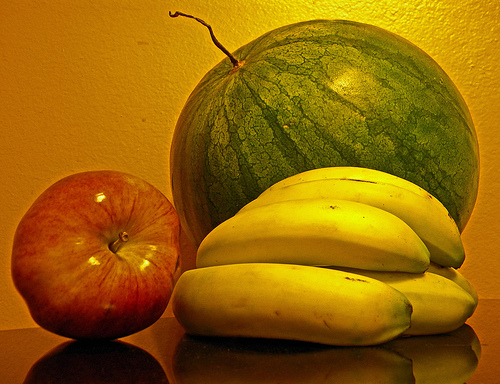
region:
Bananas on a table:
[170, 176, 485, 339]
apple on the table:
[12, 159, 184, 320]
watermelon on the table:
[158, 4, 488, 234]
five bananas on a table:
[173, 159, 497, 346]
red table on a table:
[13, 160, 203, 317]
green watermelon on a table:
[173, 15, 461, 207]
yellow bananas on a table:
[225, 186, 392, 289]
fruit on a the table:
[3, 0, 485, 324]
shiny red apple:
[16, 170, 176, 312]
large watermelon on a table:
[177, 65, 479, 216]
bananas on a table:
[177, 172, 480, 344]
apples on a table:
[12, 173, 178, 333]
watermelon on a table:
[151, 0, 486, 287]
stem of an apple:
[89, 216, 146, 258]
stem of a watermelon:
[166, 0, 246, 72]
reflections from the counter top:
[21, 340, 156, 382]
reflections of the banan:
[187, 335, 407, 380]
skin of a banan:
[381, 285, 418, 340]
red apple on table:
[1, 165, 181, 344]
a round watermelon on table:
[163, 17, 498, 264]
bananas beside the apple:
[167, 150, 484, 360]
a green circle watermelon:
[187, 5, 498, 300]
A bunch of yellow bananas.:
[173, 165, 480, 353]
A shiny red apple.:
[11, 168, 183, 339]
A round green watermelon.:
[166, 8, 481, 248]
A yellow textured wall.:
[0, 0, 499, 327]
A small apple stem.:
[109, 225, 129, 253]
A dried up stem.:
[167, 8, 244, 73]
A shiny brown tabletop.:
[0, 296, 499, 382]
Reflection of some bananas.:
[173, 323, 480, 382]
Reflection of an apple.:
[21, 335, 172, 382]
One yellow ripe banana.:
[172, 262, 412, 345]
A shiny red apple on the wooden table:
[13, 165, 185, 350]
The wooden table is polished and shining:
[8, 321, 498, 382]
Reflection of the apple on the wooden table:
[44, 328, 158, 383]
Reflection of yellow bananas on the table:
[183, 335, 498, 373]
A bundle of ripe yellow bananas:
[169, 162, 492, 348]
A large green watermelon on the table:
[167, 20, 488, 282]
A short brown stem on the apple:
[109, 223, 133, 252]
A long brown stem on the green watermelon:
[162, 0, 249, 70]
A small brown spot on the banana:
[342, 273, 373, 288]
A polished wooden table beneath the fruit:
[5, 327, 497, 381]